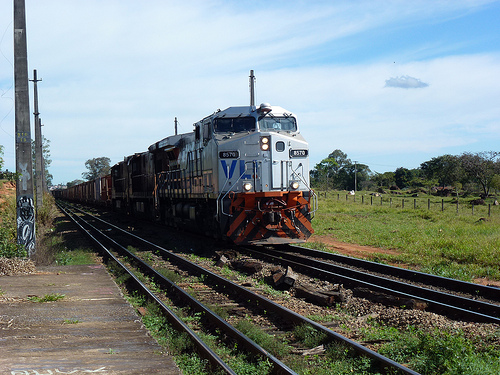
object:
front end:
[200, 69, 318, 245]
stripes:
[226, 191, 315, 245]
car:
[51, 69, 318, 245]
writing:
[223, 152, 236, 158]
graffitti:
[16, 194, 36, 258]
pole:
[12, 0, 37, 260]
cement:
[39, 295, 102, 322]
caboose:
[147, 69, 318, 245]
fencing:
[318, 192, 490, 218]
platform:
[2, 249, 101, 374]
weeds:
[26, 291, 65, 303]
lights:
[242, 181, 254, 193]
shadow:
[41, 212, 214, 263]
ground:
[46, 236, 473, 374]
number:
[289, 148, 308, 158]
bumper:
[226, 190, 315, 246]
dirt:
[321, 302, 418, 327]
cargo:
[50, 174, 112, 203]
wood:
[295, 282, 344, 306]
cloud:
[381, 74, 429, 89]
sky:
[0, 1, 497, 191]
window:
[215, 116, 297, 132]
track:
[54, 199, 500, 375]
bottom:
[57, 197, 223, 244]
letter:
[220, 160, 237, 180]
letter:
[240, 160, 252, 180]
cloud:
[348, 97, 482, 144]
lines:
[221, 240, 499, 322]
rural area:
[0, 147, 484, 375]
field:
[398, 212, 485, 247]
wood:
[228, 259, 263, 274]